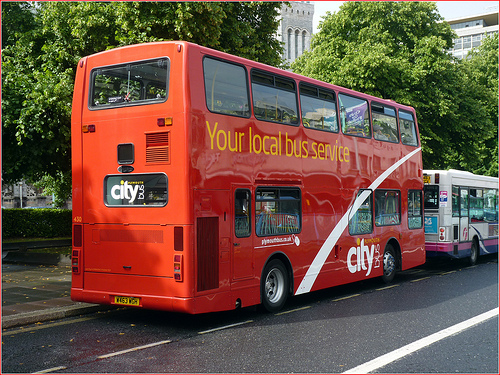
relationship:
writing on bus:
[207, 93, 368, 169] [50, 18, 452, 323]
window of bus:
[187, 62, 451, 134] [50, 18, 452, 323]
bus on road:
[50, 18, 452, 323] [58, 254, 483, 359]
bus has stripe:
[50, 18, 452, 323] [263, 143, 436, 289]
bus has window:
[50, 18, 452, 323] [187, 62, 451, 134]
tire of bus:
[264, 255, 300, 310] [50, 18, 452, 323]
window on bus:
[187, 62, 451, 134] [50, 18, 452, 323]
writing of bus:
[207, 93, 368, 169] [50, 18, 452, 323]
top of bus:
[123, 56, 406, 126] [50, 18, 452, 323]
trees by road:
[10, 52, 73, 180] [58, 254, 483, 359]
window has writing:
[187, 62, 451, 134] [207, 93, 368, 169]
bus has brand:
[50, 18, 452, 323] [337, 224, 400, 286]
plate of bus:
[87, 285, 153, 311] [50, 18, 452, 323]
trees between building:
[10, 52, 73, 180] [271, 5, 319, 76]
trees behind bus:
[10, 52, 73, 180] [50, 18, 452, 323]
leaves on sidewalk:
[24, 97, 64, 141] [3, 251, 417, 333]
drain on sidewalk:
[3, 267, 61, 324] [3, 251, 417, 333]